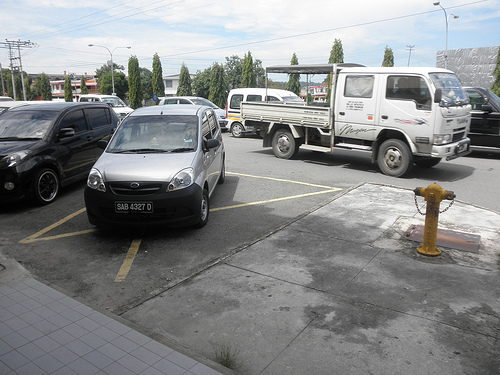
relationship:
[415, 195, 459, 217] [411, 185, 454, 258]
chain on hydrant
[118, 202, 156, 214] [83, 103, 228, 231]
license plate on car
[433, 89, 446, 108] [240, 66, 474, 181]
mirror on truck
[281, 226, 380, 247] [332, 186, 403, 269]
crack in pavement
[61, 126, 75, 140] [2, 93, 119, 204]
mirror of car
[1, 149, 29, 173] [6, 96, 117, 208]
headlight of car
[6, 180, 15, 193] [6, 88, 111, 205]
fog light of car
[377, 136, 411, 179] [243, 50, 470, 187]
tire of truck